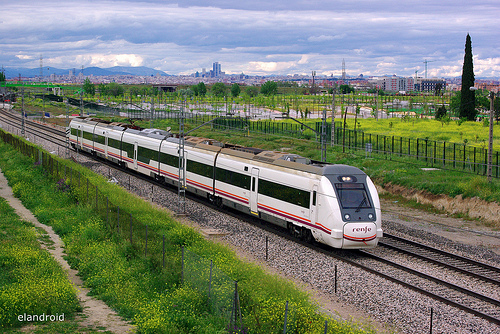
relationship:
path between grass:
[394, 221, 490, 328] [6, 138, 308, 332]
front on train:
[324, 163, 385, 254] [65, 114, 384, 254]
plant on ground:
[0, 127, 357, 333] [5, 82, 499, 332]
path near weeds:
[44, 214, 124, 326] [6, 242, 75, 320]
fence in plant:
[2, 96, 498, 333] [0, 127, 357, 333]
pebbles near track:
[292, 251, 317, 272] [7, 107, 497, 328]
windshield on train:
[341, 181, 372, 214] [53, 104, 393, 265]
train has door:
[65, 114, 384, 254] [244, 160, 260, 209]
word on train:
[346, 224, 375, 234] [65, 114, 384, 254]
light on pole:
[133, 87, 145, 99] [7, 74, 193, 227]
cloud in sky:
[4, 1, 497, 100] [1, 2, 499, 82]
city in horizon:
[233, 73, 445, 83] [6, 69, 486, 101]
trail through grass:
[6, 180, 126, 332] [2, 150, 175, 330]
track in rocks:
[7, 107, 497, 328] [321, 224, 481, 333]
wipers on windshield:
[346, 187, 369, 210] [341, 181, 372, 214]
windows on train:
[142, 149, 220, 176] [65, 114, 384, 254]